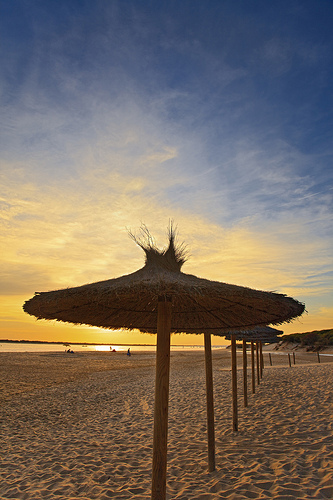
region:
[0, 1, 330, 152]
blue of daytime sky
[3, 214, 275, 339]
sunlight on thin clouds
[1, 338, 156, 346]
strip of land on horizon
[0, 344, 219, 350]
light reflection on water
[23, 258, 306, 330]
top of thatched umbrella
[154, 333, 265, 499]
poles in beach sand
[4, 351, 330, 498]
footprints on sand surface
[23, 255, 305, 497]
row of beach umbrellas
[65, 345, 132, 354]
people on sandy beach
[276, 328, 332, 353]
grass on sandy bluff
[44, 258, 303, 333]
hit made out of bamboo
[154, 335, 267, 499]
long poles holding up huts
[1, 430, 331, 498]
foot prints in the sand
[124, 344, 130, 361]
person walking on the sand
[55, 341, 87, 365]
people lying under a hut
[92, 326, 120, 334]
sun setting over water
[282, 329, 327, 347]
trees in the distance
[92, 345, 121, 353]
reflection of sun on water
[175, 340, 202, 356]
people along the beach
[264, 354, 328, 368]
four empty poles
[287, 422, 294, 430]
part of the shore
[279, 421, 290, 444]
part of the beach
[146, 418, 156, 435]
edge of a post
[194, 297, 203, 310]
part of a roof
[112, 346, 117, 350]
part of an ocean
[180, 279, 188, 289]
edge of a roof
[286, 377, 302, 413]
part of the beach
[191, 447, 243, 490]
edge of a pole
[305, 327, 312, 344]
edge of a rock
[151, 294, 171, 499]
The closest wood pole on a umbrella.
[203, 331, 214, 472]
Second closest wood pole.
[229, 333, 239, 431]
Third closest wood pole.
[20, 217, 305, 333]
The closest umbrella top.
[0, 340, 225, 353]
A thin strip of water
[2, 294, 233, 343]
Bright orange sky.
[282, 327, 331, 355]
Green grassy hillside.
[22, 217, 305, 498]
A beach umbrella with long wood pole.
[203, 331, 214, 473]
Second closest pole made of wood.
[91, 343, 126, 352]
Large white reflection on the water.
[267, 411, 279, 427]
part of the beach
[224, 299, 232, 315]
part of a roof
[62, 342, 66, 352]
part of a horizon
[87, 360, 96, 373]
part of a beach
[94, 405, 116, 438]
edge of a beach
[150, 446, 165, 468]
edge of a post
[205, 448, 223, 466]
part of a pole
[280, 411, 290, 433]
part of a sand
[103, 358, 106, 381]
part of the sun